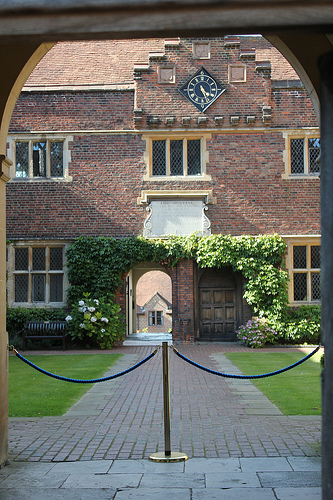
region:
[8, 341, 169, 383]
a blue rope connected to a gold post.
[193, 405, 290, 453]
the sidewalk is made of reddish colored bricks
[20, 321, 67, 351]
a black metal bench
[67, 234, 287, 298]
green foliage lines the archway.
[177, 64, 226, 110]
a black and gold diamond shaped clock.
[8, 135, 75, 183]
the middle window pane is open.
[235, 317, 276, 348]
a bush of pink flowers.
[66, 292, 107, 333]
a bunch of white flowers.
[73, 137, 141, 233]
a brick wall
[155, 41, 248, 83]
three small square windows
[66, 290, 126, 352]
Bush with big white flowers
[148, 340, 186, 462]
Pole holding rope barriers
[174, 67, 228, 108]
Clock high up on the old building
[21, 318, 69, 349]
Comfortable bench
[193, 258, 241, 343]
Closed old wooden door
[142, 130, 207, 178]
Three paneled window with fishnet pattern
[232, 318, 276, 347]
Small bush with purple flowers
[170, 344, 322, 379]
Blue barrier rope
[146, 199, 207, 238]
Plaque describing building details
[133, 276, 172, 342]
Smaller building visible through open walkway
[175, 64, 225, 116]
Square clock on building front.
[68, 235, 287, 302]
Ivy growing up building.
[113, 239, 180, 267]
Ivy growing over doorway.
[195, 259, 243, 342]
Closed wooden door.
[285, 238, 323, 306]
Framed window to building.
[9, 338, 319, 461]
Blue separation barrier.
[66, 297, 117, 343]
Carnation bush in front of building.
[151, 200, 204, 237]
Scroll shaped ornament over door.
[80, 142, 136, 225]
Section of brick building.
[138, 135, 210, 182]
Upper yellow framed window.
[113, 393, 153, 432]
this is a foot path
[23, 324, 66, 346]
this is a bench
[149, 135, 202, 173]
this is a window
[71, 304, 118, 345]
this is a flower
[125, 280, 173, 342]
this is a door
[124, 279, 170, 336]
the door is opened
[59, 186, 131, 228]
this is a wall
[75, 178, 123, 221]
the wall is made of bricks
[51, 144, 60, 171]
the window pane is shinny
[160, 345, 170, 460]
the pole is shinny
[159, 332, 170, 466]
There is a gold post near the sprawling estate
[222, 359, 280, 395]
There is blue rope that serves as a barrier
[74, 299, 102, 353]
There are prodigious white flowers growing on the wall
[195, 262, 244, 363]
There is a brown door that is near the entryway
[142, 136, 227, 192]
There is a large window in the building above the door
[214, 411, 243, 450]
The brick of the walkway is off red in color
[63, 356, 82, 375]
The grass is a light green color and looks watered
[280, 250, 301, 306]
The frame of the window looks to be a faded yellow color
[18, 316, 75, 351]
There is a bench next to the crawling white flowers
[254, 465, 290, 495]
The other tile in front of the building is black